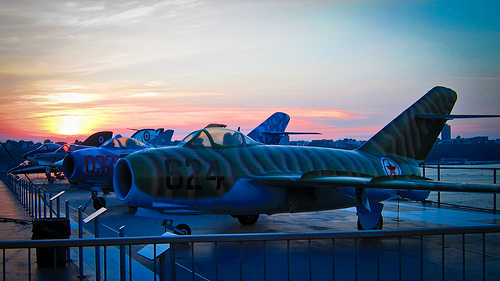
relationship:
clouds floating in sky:
[0, 1, 219, 47] [0, 0, 500, 151]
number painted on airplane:
[164, 155, 227, 192] [113, 85, 499, 234]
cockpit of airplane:
[180, 125, 261, 147] [113, 85, 499, 234]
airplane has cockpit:
[113, 85, 499, 234] [180, 125, 261, 147]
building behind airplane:
[442, 122, 453, 140] [113, 85, 499, 234]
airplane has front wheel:
[113, 85, 499, 234] [173, 224, 191, 235]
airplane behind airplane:
[61, 128, 152, 211] [113, 85, 499, 234]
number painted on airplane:
[85, 153, 125, 177] [61, 128, 152, 211]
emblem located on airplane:
[379, 155, 402, 175] [113, 85, 499, 234]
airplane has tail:
[113, 85, 499, 234] [354, 87, 458, 161]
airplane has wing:
[113, 85, 499, 234] [251, 170, 499, 193]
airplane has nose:
[113, 85, 499, 234] [113, 155, 158, 206]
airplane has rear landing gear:
[113, 85, 499, 234] [356, 203, 384, 229]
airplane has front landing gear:
[113, 85, 499, 234] [160, 220, 191, 236]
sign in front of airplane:
[82, 206, 108, 224] [113, 85, 499, 234]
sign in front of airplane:
[49, 190, 66, 201] [61, 128, 152, 211]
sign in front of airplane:
[137, 231, 182, 260] [113, 85, 499, 234]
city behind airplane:
[288, 124, 499, 161] [113, 85, 499, 234]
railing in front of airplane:
[0, 170, 209, 280] [113, 85, 499, 234]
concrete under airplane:
[15, 173, 499, 280] [113, 85, 499, 234]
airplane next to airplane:
[61, 128, 152, 211] [113, 85, 499, 234]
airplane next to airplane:
[13, 142, 94, 183] [61, 128, 152, 211]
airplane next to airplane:
[21, 141, 63, 158] [13, 142, 94, 183]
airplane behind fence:
[113, 85, 499, 234] [0, 223, 500, 279]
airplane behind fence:
[61, 128, 152, 211] [0, 223, 500, 279]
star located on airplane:
[384, 159, 398, 176] [113, 85, 499, 234]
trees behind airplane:
[301, 139, 360, 150] [113, 85, 499, 234]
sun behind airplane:
[45, 112, 102, 134] [21, 141, 63, 158]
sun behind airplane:
[45, 112, 102, 134] [13, 142, 94, 183]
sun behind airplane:
[45, 112, 102, 134] [61, 128, 152, 211]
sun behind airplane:
[45, 112, 102, 134] [113, 85, 499, 234]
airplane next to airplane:
[113, 85, 499, 234] [61, 128, 152, 211]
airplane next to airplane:
[61, 128, 152, 211] [13, 142, 94, 183]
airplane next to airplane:
[13, 142, 94, 183] [21, 141, 63, 158]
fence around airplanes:
[0, 223, 500, 279] [21, 85, 500, 228]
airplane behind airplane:
[21, 141, 63, 158] [13, 142, 94, 183]